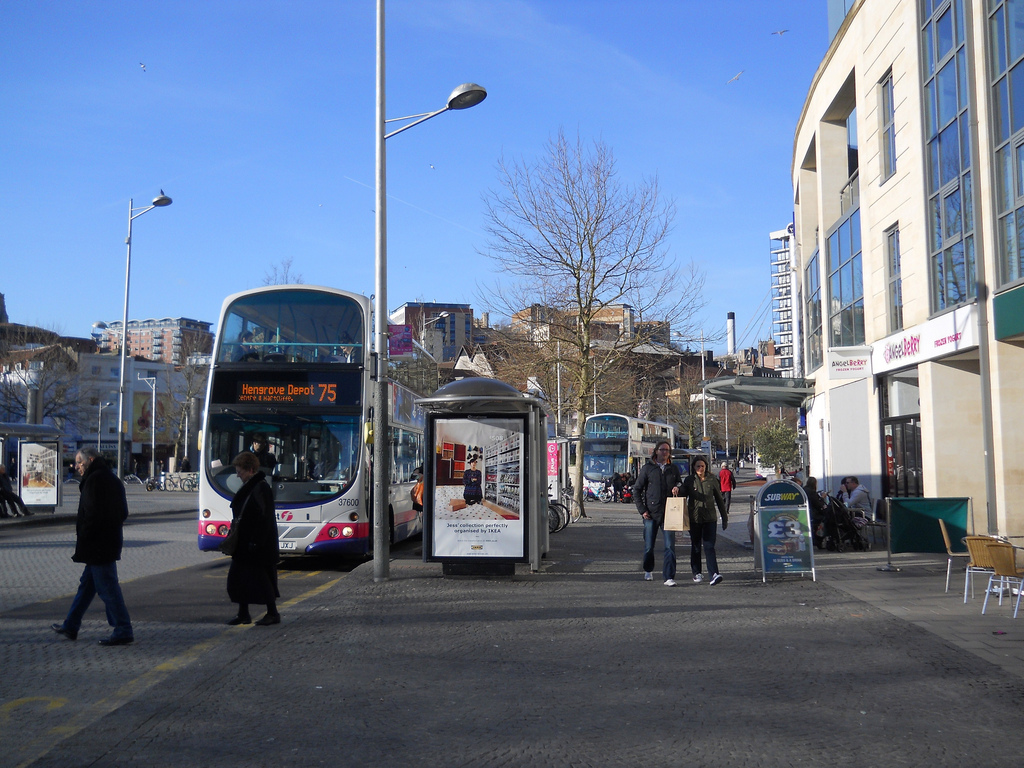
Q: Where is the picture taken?
A: At a bus stop.